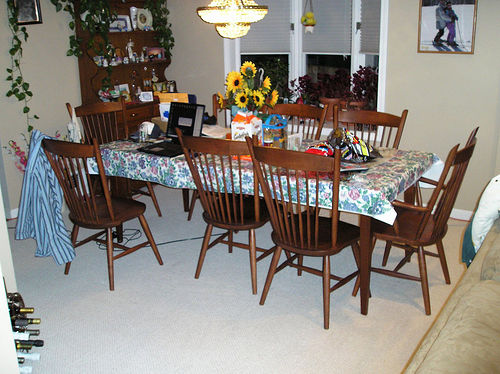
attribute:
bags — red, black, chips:
[312, 129, 384, 162]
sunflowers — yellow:
[220, 60, 348, 131]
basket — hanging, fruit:
[226, 62, 302, 164]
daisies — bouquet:
[218, 50, 295, 132]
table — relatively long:
[89, 107, 369, 239]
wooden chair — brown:
[348, 122, 481, 317]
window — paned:
[198, 5, 423, 118]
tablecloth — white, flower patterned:
[87, 136, 444, 226]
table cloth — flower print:
[75, 138, 445, 228]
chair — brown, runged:
[264, 125, 338, 272]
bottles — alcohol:
[6, 290, 43, 372]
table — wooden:
[44, 81, 486, 336]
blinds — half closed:
[234, 2, 384, 59]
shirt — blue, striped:
[10, 120, 86, 263]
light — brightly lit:
[197, 4, 270, 40]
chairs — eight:
[19, 131, 483, 310]